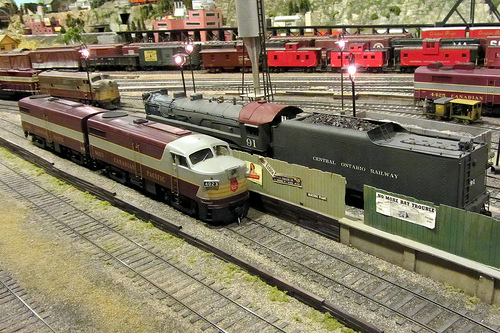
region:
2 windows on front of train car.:
[187, 145, 230, 160]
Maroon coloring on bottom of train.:
[90, 152, 145, 172]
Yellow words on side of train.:
[110, 152, 162, 185]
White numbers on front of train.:
[203, 181, 220, 190]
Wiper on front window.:
[201, 149, 216, 169]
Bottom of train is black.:
[55, 139, 140, 195]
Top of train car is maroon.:
[108, 103, 160, 145]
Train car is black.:
[293, 119, 435, 182]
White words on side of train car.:
[296, 153, 395, 184]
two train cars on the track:
[18, 93, 253, 220]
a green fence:
[363, 186, 498, 264]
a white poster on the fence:
[368, 193, 439, 228]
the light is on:
[343, 63, 358, 78]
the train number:
[203, 178, 219, 190]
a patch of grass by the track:
[261, 286, 291, 303]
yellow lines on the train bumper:
[209, 179, 247, 198]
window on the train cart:
[245, 123, 258, 138]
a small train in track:
[13, 88, 258, 240]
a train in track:
[5, 88, 312, 242]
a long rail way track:
[251, 216, 446, 331]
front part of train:
[178, 120, 276, 225]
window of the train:
[181, 127, 233, 169]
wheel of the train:
[12, 133, 222, 225]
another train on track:
[142, 88, 499, 199]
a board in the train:
[361, 180, 454, 242]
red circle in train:
[217, 172, 249, 194]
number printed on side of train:
[237, 131, 267, 150]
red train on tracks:
[332, 38, 389, 69]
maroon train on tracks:
[410, 61, 497, 98]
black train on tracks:
[303, 115, 477, 187]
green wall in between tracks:
[359, 187, 499, 252]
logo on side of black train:
[305, 140, 409, 185]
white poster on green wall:
[368, 190, 440, 227]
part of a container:
[459, 177, 467, 182]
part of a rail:
[274, 274, 280, 291]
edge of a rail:
[303, 266, 309, 273]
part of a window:
[203, 143, 210, 150]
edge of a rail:
[271, 290, 272, 294]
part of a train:
[224, 225, 233, 257]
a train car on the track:
[286, 105, 407, 219]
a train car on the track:
[168, 75, 254, 150]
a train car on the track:
[390, 44, 480, 83]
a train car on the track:
[251, 43, 334, 89]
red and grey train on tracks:
[14, 82, 264, 233]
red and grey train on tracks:
[144, 80, 491, 235]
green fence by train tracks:
[358, 182, 480, 326]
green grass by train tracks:
[174, 240, 270, 315]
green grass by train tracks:
[17, 149, 54, 186]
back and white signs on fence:
[268, 159, 345, 213]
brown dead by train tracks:
[22, 232, 150, 311]